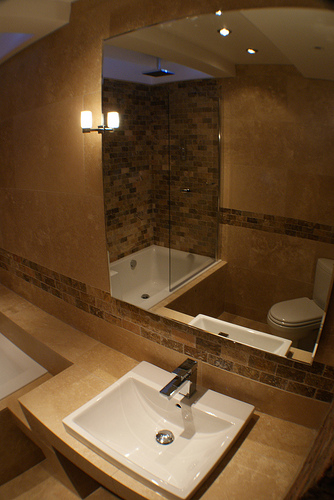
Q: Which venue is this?
A: This is a bathroom.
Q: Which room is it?
A: It is a bathroom.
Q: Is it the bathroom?
A: Yes, it is the bathroom.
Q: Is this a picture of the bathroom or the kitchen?
A: It is showing the bathroom.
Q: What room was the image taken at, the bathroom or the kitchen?
A: It was taken at the bathroom.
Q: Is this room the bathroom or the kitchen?
A: It is the bathroom.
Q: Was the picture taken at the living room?
A: No, the picture was taken in the bathroom.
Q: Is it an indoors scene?
A: Yes, it is indoors.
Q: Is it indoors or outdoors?
A: It is indoors.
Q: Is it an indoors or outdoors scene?
A: It is indoors.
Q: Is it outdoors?
A: No, it is indoors.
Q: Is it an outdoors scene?
A: No, it is indoors.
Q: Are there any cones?
A: No, there are no cones.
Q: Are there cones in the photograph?
A: No, there are no cones.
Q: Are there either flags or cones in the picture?
A: No, there are no cones or flags.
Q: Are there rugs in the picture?
A: No, there are no rugs.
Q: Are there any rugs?
A: No, there are no rugs.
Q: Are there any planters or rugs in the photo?
A: No, there are no rugs or planters.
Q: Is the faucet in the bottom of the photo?
A: Yes, the faucet is in the bottom of the image.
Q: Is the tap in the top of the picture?
A: No, the tap is in the bottom of the image.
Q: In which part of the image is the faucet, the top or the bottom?
A: The faucet is in the bottom of the image.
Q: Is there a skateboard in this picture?
A: No, there are no skateboards.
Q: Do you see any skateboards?
A: No, there are no skateboards.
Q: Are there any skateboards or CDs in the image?
A: No, there are no skateboards or cds.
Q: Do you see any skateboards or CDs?
A: No, there are no skateboards or cds.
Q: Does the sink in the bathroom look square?
A: Yes, the sink is square.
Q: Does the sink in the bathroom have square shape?
A: Yes, the sink is square.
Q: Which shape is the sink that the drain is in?
A: The sink is square.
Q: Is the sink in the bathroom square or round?
A: The sink is square.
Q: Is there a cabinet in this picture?
A: No, there are no cabinets.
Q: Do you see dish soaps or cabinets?
A: No, there are no cabinets or dish soaps.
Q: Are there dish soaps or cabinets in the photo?
A: No, there are no cabinets or dish soaps.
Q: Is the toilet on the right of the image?
A: Yes, the toilet is on the right of the image.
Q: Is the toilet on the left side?
A: No, the toilet is on the right of the image.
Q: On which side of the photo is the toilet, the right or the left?
A: The toilet is on the right of the image.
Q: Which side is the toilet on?
A: The toilet is on the right of the image.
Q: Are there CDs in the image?
A: No, there are no cds.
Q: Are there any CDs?
A: No, there are no cds.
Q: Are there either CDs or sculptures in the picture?
A: No, there are no CDs or sculptures.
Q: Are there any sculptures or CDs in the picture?
A: No, there are no CDs or sculptures.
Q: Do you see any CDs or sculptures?
A: No, there are no CDs or sculptures.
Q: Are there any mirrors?
A: Yes, there is a mirror.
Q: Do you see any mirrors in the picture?
A: Yes, there is a mirror.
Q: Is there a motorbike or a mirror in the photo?
A: Yes, there is a mirror.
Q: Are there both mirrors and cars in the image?
A: No, there is a mirror but no cars.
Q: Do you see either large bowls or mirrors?
A: Yes, there is a large mirror.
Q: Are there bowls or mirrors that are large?
A: Yes, the mirror is large.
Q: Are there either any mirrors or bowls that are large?
A: Yes, the mirror is large.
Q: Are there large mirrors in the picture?
A: Yes, there is a large mirror.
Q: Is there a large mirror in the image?
A: Yes, there is a large mirror.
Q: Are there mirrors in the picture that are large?
A: Yes, there is a mirror that is large.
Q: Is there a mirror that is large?
A: Yes, there is a mirror that is large.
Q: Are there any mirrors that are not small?
A: Yes, there is a large mirror.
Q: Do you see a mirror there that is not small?
A: Yes, there is a large mirror.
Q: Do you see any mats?
A: No, there are no mats.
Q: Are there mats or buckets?
A: No, there are no mats or buckets.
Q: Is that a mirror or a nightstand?
A: That is a mirror.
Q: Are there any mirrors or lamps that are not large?
A: No, there is a mirror but it is large.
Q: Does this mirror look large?
A: Yes, the mirror is large.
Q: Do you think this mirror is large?
A: Yes, the mirror is large.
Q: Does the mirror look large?
A: Yes, the mirror is large.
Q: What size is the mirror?
A: The mirror is large.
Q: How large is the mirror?
A: The mirror is large.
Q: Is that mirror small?
A: No, the mirror is large.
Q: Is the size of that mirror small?
A: No, the mirror is large.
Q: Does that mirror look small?
A: No, the mirror is large.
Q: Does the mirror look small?
A: No, the mirror is large.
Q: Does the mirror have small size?
A: No, the mirror is large.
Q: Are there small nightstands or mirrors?
A: No, there is a mirror but it is large.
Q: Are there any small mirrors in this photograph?
A: No, there is a mirror but it is large.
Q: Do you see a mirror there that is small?
A: No, there is a mirror but it is large.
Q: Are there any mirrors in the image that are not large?
A: No, there is a mirror but it is large.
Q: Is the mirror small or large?
A: The mirror is large.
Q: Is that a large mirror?
A: Yes, that is a large mirror.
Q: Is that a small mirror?
A: No, that is a large mirror.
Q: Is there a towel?
A: No, there are no towels.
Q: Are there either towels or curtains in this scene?
A: No, there are no towels or curtains.